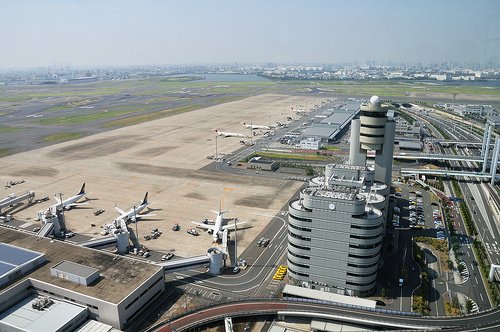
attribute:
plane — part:
[189, 203, 251, 251]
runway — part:
[205, 241, 285, 286]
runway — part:
[216, 161, 311, 184]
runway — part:
[448, 175, 498, 302]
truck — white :
[394, 275, 407, 287]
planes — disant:
[216, 119, 272, 139]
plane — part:
[184, 199, 252, 242]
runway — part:
[132, 162, 289, 190]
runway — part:
[15, 91, 322, 233]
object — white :
[356, 94, 404, 114]